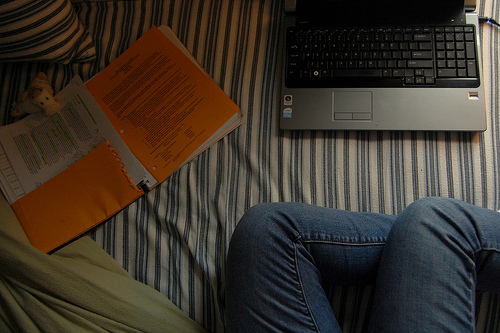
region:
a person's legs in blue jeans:
[220, 187, 497, 332]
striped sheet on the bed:
[259, 134, 390, 204]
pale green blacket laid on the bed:
[39, 229, 174, 331]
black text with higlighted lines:
[7, 103, 83, 165]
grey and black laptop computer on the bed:
[282, 0, 490, 144]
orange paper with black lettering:
[98, 45, 235, 177]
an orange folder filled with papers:
[2, 50, 245, 226]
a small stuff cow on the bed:
[7, 73, 75, 120]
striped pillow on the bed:
[2, 3, 106, 75]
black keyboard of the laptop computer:
[284, 23, 479, 91]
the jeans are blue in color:
[241, 197, 483, 312]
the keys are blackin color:
[281, 35, 471, 87]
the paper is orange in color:
[90, 65, 208, 165]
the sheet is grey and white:
[151, 190, 221, 271]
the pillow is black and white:
[25, 10, 91, 56]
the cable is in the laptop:
[471, 9, 498, 26]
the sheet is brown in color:
[16, 217, 168, 332]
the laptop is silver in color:
[288, 17, 488, 137]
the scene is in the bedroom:
[11, 10, 482, 331]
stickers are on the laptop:
[281, 95, 298, 122]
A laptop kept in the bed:
[286, 5, 486, 145]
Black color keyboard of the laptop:
[306, 35, 443, 63]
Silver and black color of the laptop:
[273, 29, 492, 154]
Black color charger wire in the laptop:
[483, 5, 497, 40]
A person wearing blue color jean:
[251, 205, 471, 305]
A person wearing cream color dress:
[48, 275, 154, 324]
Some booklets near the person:
[78, 82, 203, 154]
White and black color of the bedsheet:
[251, 153, 336, 183]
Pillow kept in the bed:
[18, 8, 80, 38]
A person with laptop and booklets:
[8, 5, 498, 317]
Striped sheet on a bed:
[48, 0, 499, 332]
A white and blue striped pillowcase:
[0, 2, 97, 68]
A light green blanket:
[0, 194, 208, 331]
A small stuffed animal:
[15, 69, 62, 116]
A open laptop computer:
[271, 0, 486, 137]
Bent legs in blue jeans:
[221, 194, 499, 330]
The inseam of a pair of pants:
[288, 229, 391, 332]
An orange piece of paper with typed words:
[82, 22, 242, 187]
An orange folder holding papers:
[0, 22, 245, 258]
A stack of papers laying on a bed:
[0, 22, 243, 257]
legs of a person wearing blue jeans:
[211, 188, 495, 330]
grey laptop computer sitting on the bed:
[283, 0, 489, 141]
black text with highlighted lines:
[23, 110, 100, 158]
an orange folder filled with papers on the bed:
[6, 58, 231, 215]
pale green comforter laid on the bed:
[12, 245, 179, 331]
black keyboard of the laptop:
[274, 18, 480, 88]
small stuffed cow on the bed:
[13, 73, 68, 125]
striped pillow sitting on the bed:
[2, 0, 101, 72]